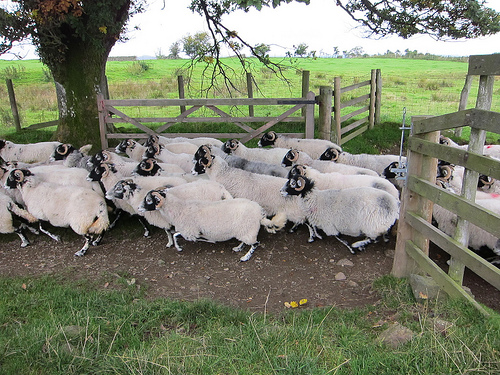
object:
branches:
[192, 1, 302, 111]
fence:
[384, 53, 498, 329]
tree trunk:
[31, 2, 128, 142]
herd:
[0, 133, 500, 262]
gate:
[324, 68, 383, 145]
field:
[0, 57, 500, 133]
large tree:
[0, 0, 500, 139]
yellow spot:
[89, 215, 101, 227]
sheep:
[3, 169, 109, 257]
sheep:
[280, 177, 401, 253]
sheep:
[189, 150, 298, 229]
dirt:
[244, 258, 303, 286]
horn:
[294, 177, 305, 191]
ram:
[280, 174, 397, 255]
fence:
[96, 67, 382, 156]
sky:
[134, 2, 496, 51]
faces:
[280, 177, 296, 198]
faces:
[144, 144, 153, 159]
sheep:
[206, 156, 290, 232]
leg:
[352, 237, 379, 248]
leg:
[138, 217, 149, 239]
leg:
[13, 230, 30, 248]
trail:
[0, 223, 402, 310]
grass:
[80, 280, 235, 370]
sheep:
[106, 177, 186, 239]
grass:
[423, 59, 500, 131]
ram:
[7, 169, 108, 254]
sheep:
[257, 131, 342, 159]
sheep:
[317, 146, 408, 175]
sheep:
[137, 190, 262, 258]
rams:
[0, 140, 63, 161]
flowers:
[299, 298, 308, 305]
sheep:
[128, 160, 207, 189]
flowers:
[284, 301, 291, 307]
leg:
[240, 238, 260, 262]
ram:
[137, 188, 265, 262]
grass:
[1, 61, 155, 145]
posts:
[83, 71, 367, 137]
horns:
[151, 192, 164, 208]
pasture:
[7, 58, 483, 116]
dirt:
[0, 240, 163, 318]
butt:
[71, 187, 115, 257]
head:
[137, 190, 166, 213]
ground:
[80, 246, 235, 373]